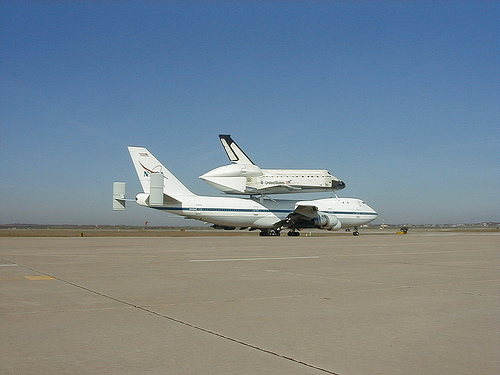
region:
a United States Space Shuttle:
[199, 133, 349, 199]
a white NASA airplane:
[111, 145, 379, 235]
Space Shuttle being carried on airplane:
[111, 133, 380, 239]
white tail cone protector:
[200, 162, 245, 193]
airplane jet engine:
[311, 214, 336, 229]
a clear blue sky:
[1, 0, 498, 225]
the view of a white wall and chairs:
[276, 268, 286, 292]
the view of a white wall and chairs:
[282, 318, 299, 354]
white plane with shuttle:
[82, 125, 386, 250]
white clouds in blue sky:
[355, 61, 396, 112]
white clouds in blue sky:
[390, 171, 467, 226]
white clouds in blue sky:
[38, 155, 60, 166]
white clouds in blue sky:
[84, 53, 136, 88]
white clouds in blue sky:
[228, 35, 292, 67]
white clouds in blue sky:
[95, 33, 165, 77]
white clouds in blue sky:
[360, 81, 397, 106]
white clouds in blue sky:
[291, 93, 366, 127]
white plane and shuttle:
[120, 135, 372, 253]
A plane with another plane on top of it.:
[107, 125, 381, 235]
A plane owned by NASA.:
[106, 141, 383, 238]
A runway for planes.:
[1, 233, 498, 374]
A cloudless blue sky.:
[2, 4, 499, 222]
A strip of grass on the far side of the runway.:
[4, 228, 497, 238]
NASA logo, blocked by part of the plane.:
[138, 161, 170, 183]